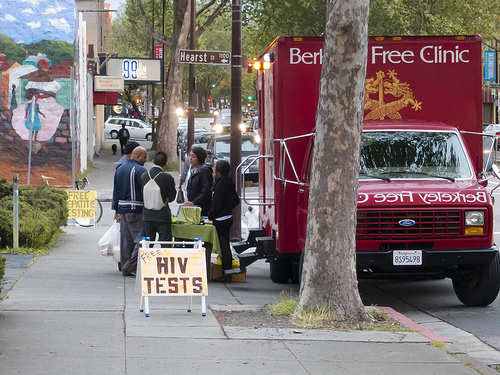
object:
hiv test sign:
[139, 247, 208, 297]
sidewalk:
[1, 144, 500, 375]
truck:
[251, 32, 500, 309]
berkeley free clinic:
[287, 46, 472, 66]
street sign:
[178, 49, 233, 65]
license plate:
[392, 249, 423, 265]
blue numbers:
[395, 256, 399, 263]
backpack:
[142, 170, 168, 211]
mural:
[1, 0, 82, 188]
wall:
[1, 0, 71, 189]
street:
[368, 276, 500, 350]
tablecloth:
[171, 223, 223, 260]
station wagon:
[104, 116, 158, 142]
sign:
[62, 190, 98, 219]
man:
[140, 151, 176, 250]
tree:
[287, 0, 372, 328]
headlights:
[215, 127, 224, 132]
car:
[209, 114, 247, 136]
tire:
[452, 248, 500, 307]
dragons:
[364, 68, 423, 121]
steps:
[234, 251, 262, 269]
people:
[116, 121, 132, 155]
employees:
[207, 158, 241, 284]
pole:
[228, 0, 241, 244]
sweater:
[140, 166, 177, 224]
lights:
[463, 209, 486, 227]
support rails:
[242, 155, 274, 206]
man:
[109, 145, 151, 278]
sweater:
[111, 158, 149, 215]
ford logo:
[399, 218, 416, 226]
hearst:
[180, 51, 208, 62]